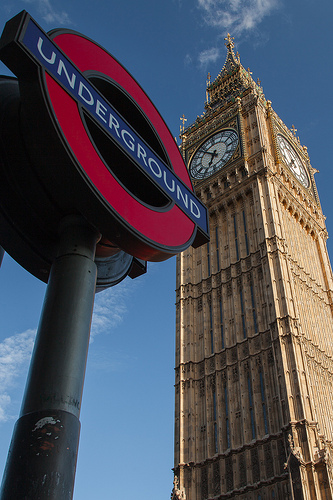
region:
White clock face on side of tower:
[186, 125, 241, 180]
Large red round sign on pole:
[2, 9, 211, 498]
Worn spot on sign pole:
[17, 414, 71, 496]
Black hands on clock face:
[198, 148, 221, 167]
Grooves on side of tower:
[172, 174, 301, 498]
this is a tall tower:
[169, 38, 329, 497]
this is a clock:
[180, 125, 247, 183]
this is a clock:
[278, 121, 319, 189]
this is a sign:
[1, 13, 217, 266]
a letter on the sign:
[189, 194, 207, 225]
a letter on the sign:
[171, 180, 191, 209]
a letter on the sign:
[146, 152, 165, 181]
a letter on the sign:
[116, 123, 136, 155]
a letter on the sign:
[119, 126, 140, 155]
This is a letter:
[34, 26, 57, 73]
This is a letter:
[76, 71, 95, 110]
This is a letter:
[94, 93, 109, 123]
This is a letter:
[105, 108, 120, 138]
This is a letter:
[120, 122, 136, 154]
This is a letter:
[136, 137, 149, 168]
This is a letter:
[148, 150, 163, 185]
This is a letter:
[161, 165, 178, 195]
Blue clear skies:
[121, 318, 169, 424]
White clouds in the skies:
[100, 286, 119, 324]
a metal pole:
[30, 292, 100, 484]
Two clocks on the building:
[194, 115, 319, 185]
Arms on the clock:
[197, 142, 226, 165]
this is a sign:
[13, 25, 221, 260]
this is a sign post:
[0, 247, 106, 496]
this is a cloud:
[94, 302, 126, 336]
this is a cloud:
[206, 10, 278, 43]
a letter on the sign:
[36, 38, 56, 71]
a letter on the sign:
[106, 111, 122, 141]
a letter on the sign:
[106, 108, 121, 136]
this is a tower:
[158, 21, 324, 488]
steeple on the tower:
[179, 9, 271, 119]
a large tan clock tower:
[173, 25, 331, 493]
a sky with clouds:
[5, 1, 332, 486]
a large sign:
[1, 6, 226, 498]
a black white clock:
[182, 127, 248, 183]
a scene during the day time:
[4, 5, 325, 455]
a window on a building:
[198, 422, 205, 432]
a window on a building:
[248, 408, 252, 412]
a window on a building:
[258, 401, 266, 411]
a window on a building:
[224, 317, 238, 323]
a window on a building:
[254, 303, 264, 305]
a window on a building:
[193, 256, 200, 263]